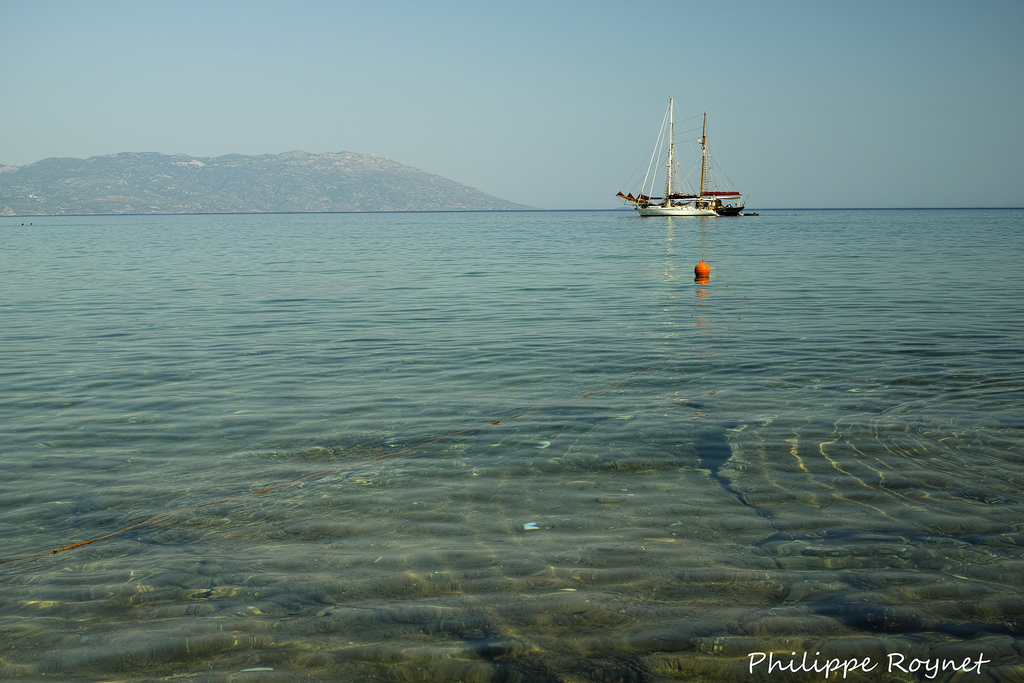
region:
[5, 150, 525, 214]
a hill in the distance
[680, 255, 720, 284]
an orange buoy in the water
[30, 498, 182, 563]
a stick floating in the water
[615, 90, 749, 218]
a white boat in the distance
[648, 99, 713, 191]
tall masts on the boat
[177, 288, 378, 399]
ripples in the surface of the water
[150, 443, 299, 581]
the water is very clear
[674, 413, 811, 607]
cracks in the rock beneath the water's surface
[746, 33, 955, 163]
the sky is bluish-grey and clear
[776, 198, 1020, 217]
dark line dividing the water from the sky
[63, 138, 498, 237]
A hill is in the distance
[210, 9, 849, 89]
The sky is clear and blue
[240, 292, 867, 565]
The water has very light ripples on it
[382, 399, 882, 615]
The ground can be seen in the water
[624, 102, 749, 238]
A boat is on the water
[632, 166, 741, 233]
A boat is white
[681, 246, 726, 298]
An object is floating on the water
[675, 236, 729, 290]
An object is orange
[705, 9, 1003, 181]
The sky is cloudless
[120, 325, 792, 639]
The water is a little murky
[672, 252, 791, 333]
orange flotation device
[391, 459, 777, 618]
fish swimming under the surface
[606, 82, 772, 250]
white ship in the distance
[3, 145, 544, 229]
elevated mountain near the horizon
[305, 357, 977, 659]
water surface rippling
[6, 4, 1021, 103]
clear sky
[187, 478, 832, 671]
rocky water ground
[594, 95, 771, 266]
Schooner not moving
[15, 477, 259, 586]
rope connected to flotation device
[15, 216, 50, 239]
Objects on surface in far background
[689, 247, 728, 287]
an orange bouy in the water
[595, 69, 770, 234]
a sailboat several hundred yards from shore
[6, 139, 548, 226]
a mid-sized island in the distance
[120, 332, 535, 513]
gently rippling and very clear ocean water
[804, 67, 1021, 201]
blue sky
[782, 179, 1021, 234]
the horizon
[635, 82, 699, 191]
the mast of the sailboat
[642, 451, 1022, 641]
rocks visible below the water's surface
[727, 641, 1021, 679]
the signature of the photographer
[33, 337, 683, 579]
the orange rope leading to the buoy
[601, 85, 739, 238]
Boat sitting in the water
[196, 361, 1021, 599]
Ripples in the water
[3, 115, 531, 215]
Island in the background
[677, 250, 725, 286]
orange round buoy in the water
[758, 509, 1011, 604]
rocks at the bottom of the water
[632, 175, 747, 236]
the boat is white color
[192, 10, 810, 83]
blue clear sky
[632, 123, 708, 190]
Brown mast for sail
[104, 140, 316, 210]
trees on the island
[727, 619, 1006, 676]
White letters in a name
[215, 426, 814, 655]
Water appears very clear.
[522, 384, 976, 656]
There appears to be green growth and curving tracks under the water.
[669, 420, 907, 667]
There appear to be fissures between areas of green growth.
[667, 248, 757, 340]
An orange buoy in the distance.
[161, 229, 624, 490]
The water shows minimal rippling.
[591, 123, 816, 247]
There is a boat in the distance.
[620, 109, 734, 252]
It is white and shows no sails.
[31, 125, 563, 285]
A mountainous land mass appears to the left.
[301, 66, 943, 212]
The sky's slate-blue color seems to indicate an overcast day.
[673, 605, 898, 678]
The artist has signed this photo.